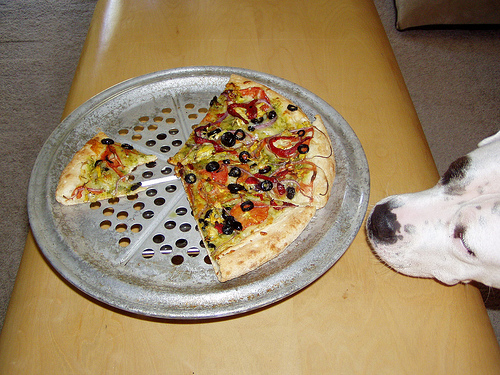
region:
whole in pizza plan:
[115, 236, 131, 248]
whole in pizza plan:
[128, 220, 142, 234]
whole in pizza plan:
[141, 210, 154, 221]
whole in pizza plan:
[151, 195, 166, 206]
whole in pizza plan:
[146, 186, 157, 198]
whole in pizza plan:
[99, 218, 110, 231]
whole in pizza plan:
[114, 223, 127, 236]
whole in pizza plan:
[116, 208, 131, 222]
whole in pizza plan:
[131, 200, 146, 212]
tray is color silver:
[22, 55, 375, 326]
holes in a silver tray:
[94, 194, 186, 261]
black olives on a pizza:
[217, 188, 253, 238]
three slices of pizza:
[169, 66, 342, 286]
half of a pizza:
[49, 123, 168, 208]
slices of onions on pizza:
[261, 126, 326, 191]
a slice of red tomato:
[224, 196, 275, 228]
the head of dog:
[367, 120, 498, 296]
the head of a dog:
[362, 122, 499, 295]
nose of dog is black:
[368, 200, 400, 247]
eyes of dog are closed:
[436, 152, 481, 261]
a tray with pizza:
[23, 55, 371, 330]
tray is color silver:
[16, 58, 381, 325]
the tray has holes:
[21, 53, 378, 326]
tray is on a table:
[7, 30, 382, 346]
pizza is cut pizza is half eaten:
[51, 120, 160, 216]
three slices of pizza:
[164, 63, 342, 289]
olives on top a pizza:
[183, 93, 304, 253]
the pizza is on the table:
[12, 45, 377, 317]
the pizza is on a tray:
[2, 35, 382, 344]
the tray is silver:
[12, 61, 380, 338]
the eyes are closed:
[430, 150, 486, 272]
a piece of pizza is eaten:
[35, 94, 172, 206]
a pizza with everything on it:
[159, 62, 332, 254]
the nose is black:
[352, 199, 410, 275]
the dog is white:
[365, 126, 487, 299]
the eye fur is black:
[413, 134, 480, 198]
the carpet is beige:
[2, 0, 72, 69]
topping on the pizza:
[243, 215, 263, 232]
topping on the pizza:
[252, 212, 272, 227]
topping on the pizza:
[270, 116, 286, 131]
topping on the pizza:
[224, 183, 238, 195]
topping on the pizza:
[203, 159, 227, 174]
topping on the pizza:
[213, 173, 228, 189]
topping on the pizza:
[226, 222, 242, 241]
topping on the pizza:
[207, 162, 222, 182]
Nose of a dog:
[370, 199, 401, 249]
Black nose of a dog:
[368, 201, 403, 249]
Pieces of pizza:
[53, 72, 336, 290]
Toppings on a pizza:
[208, 126, 282, 211]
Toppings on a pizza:
[216, 146, 291, 201]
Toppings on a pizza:
[96, 137, 143, 189]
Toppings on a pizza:
[193, 144, 283, 231]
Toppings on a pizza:
[206, 114, 281, 196]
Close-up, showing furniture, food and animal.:
[2, 65, 498, 368]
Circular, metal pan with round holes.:
[37, 75, 364, 311]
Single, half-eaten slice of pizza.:
[60, 127, 149, 217]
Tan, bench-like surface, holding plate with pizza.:
[8, 277, 487, 374]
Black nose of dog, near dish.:
[364, 200, 404, 261]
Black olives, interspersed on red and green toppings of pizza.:
[205, 124, 275, 236]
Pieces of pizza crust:
[29, 66, 370, 321]